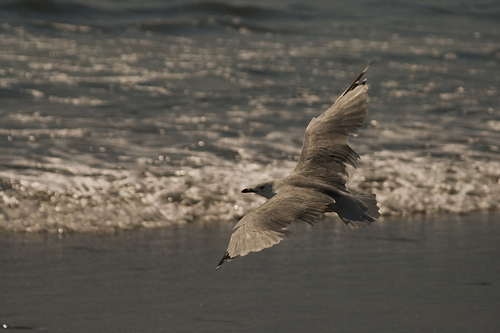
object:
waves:
[475, 160, 495, 177]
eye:
[260, 186, 265, 189]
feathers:
[362, 61, 375, 78]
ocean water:
[154, 106, 185, 122]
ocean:
[56, 12, 422, 66]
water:
[163, 181, 188, 190]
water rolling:
[189, 173, 215, 221]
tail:
[337, 185, 382, 229]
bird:
[213, 57, 380, 269]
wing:
[214, 190, 336, 270]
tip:
[214, 253, 234, 268]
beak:
[241, 186, 253, 194]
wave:
[215, 142, 239, 164]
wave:
[147, 18, 184, 32]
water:
[61, 0, 72, 12]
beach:
[0, 207, 500, 331]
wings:
[288, 65, 371, 181]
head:
[241, 179, 275, 201]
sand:
[141, 233, 156, 242]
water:
[0, 0, 18, 12]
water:
[4, 200, 26, 213]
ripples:
[49, 196, 66, 211]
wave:
[434, 139, 462, 156]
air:
[5, 0, 497, 329]